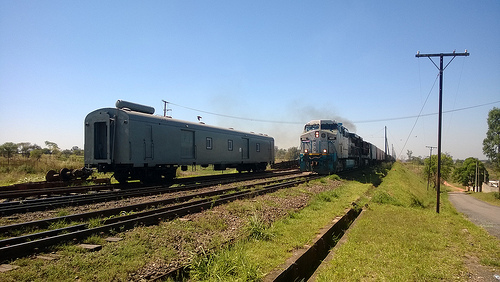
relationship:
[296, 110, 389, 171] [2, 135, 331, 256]
train traveling on rails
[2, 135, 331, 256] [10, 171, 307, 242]
rails covered with grass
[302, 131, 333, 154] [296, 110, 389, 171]
headlights on train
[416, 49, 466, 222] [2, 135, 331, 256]
utility pole near rails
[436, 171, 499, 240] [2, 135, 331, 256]
road near rails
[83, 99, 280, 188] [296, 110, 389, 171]
train car beside train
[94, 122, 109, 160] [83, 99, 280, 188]
door of train car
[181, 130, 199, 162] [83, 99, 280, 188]
door of train car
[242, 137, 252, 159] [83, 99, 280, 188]
door of train car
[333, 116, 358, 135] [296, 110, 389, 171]
smoke coming out of train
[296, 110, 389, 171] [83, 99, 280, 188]
train beside train car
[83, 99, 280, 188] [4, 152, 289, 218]
train car on tracks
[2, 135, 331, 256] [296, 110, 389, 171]
rails for train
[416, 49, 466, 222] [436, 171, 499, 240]
utility pole next to road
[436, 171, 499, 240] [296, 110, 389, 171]
road next to train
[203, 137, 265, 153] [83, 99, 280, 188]
windows on train car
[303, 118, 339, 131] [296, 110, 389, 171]
windshield on train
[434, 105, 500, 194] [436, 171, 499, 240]
trees beside road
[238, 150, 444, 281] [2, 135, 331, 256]
grass growing by rails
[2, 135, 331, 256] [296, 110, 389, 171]
rails used by train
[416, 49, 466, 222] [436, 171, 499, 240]
utility pole by side of road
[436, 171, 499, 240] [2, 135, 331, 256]
road beside rails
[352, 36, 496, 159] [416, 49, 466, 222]
power line on utility pole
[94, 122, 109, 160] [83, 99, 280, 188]
door for train car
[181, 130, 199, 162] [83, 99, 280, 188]
door for train car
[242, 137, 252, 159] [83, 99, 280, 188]
door for train car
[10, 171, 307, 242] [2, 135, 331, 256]
grass overgrown on rails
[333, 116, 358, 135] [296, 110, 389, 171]
smoke from train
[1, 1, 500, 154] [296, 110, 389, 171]
sky above train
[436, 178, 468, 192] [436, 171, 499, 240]
trail beside road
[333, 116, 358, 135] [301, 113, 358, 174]
smoke coming from engine car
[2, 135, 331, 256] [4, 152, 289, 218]
rails by tracks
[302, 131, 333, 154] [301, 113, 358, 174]
headlights on engine car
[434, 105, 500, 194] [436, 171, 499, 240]
trees next to a road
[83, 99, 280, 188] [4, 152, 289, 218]
train car parked on tracks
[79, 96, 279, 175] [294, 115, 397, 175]
locomotive pulling train